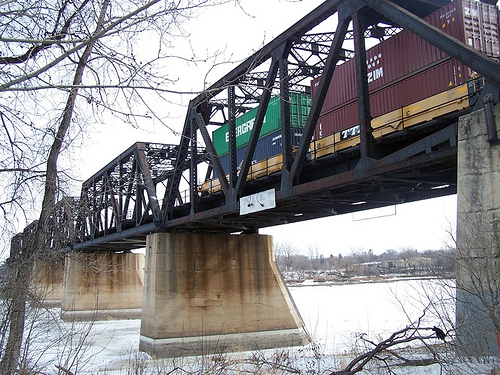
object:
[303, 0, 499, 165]
crate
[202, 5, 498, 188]
train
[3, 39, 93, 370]
trees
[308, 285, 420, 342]
snow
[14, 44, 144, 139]
branches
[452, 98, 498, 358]
pillar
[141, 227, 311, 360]
pillar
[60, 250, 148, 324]
pillar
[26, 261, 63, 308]
pillar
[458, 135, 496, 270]
pillars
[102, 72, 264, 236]
bridge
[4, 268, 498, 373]
river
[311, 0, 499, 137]
containers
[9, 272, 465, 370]
white snow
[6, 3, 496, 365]
bridge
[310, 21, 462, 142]
car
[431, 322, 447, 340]
object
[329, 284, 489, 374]
branches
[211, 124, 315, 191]
crate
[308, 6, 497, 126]
train car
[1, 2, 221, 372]
tree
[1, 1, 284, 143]
sky